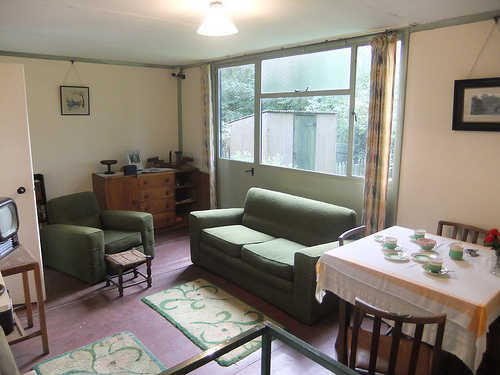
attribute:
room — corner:
[110, 99, 471, 358]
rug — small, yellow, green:
[26, 332, 165, 374]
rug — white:
[143, 277, 286, 365]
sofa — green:
[187, 184, 356, 326]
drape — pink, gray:
[364, 34, 396, 233]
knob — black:
[18, 187, 26, 195]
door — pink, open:
[0, 63, 49, 306]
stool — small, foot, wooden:
[104, 250, 153, 295]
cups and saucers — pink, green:
[376, 227, 478, 279]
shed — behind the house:
[230, 108, 336, 173]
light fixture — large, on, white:
[197, 1, 237, 38]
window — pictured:
[216, 44, 374, 178]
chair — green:
[42, 191, 153, 283]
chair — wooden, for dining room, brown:
[343, 298, 447, 373]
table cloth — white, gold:
[316, 228, 499, 372]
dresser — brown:
[95, 171, 174, 225]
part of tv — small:
[1, 197, 21, 258]